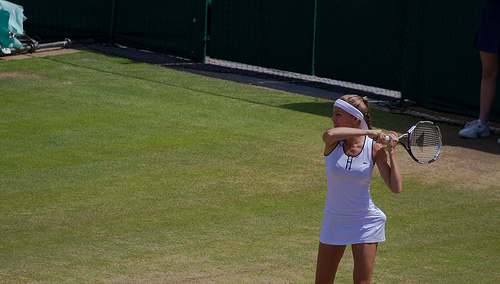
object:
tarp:
[0, 1, 29, 56]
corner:
[0, 0, 27, 56]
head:
[330, 94, 372, 138]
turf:
[1, 50, 495, 282]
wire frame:
[410, 123, 442, 161]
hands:
[366, 129, 387, 143]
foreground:
[0, 35, 493, 284]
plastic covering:
[0, 1, 33, 53]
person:
[454, 0, 500, 146]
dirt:
[383, 125, 500, 190]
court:
[2, 44, 499, 284]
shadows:
[275, 85, 500, 157]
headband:
[333, 98, 368, 136]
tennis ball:
[370, 210, 387, 223]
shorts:
[316, 205, 388, 246]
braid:
[359, 95, 373, 131]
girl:
[313, 93, 402, 284]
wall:
[93, 0, 499, 150]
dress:
[314, 135, 387, 246]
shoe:
[457, 119, 492, 139]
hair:
[333, 94, 373, 131]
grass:
[0, 47, 500, 284]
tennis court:
[2, 0, 497, 284]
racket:
[371, 121, 442, 165]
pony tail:
[361, 95, 373, 140]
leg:
[456, 44, 498, 138]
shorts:
[467, 11, 500, 55]